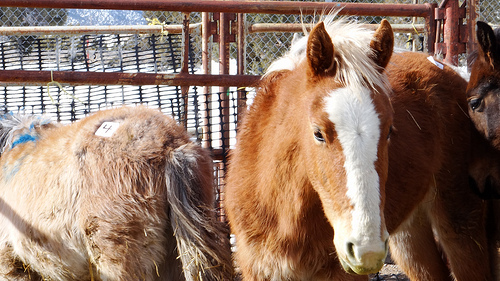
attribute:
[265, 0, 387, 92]
mane — White 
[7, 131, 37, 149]
spot — blue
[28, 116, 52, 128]
spot — blue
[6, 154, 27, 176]
spot — blue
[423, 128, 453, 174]
ground —  soft looking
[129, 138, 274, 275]
tail — edge of 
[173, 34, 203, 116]
rail — part of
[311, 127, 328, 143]
eye — open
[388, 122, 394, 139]
eye — open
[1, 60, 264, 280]
rail — part 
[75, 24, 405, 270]
winter — season 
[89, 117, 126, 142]
number — four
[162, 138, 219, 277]
tail — fluffy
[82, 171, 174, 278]
leg — back of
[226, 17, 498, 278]
horse — brown and white, brown, white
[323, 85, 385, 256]
patch — bright, white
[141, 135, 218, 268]
tail — grey and tan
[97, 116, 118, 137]
shaved spot —  white 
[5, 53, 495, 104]
pole —  rusted 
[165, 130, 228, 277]
tail — part of 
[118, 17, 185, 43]
pipe — rusty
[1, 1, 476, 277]
fence — rusty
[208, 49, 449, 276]
horse — brown and white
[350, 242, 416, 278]
tip — brown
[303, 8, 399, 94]
mane — white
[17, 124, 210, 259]
fur — shaggy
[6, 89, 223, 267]
pony —  fluffy 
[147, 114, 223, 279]
tail — grey 